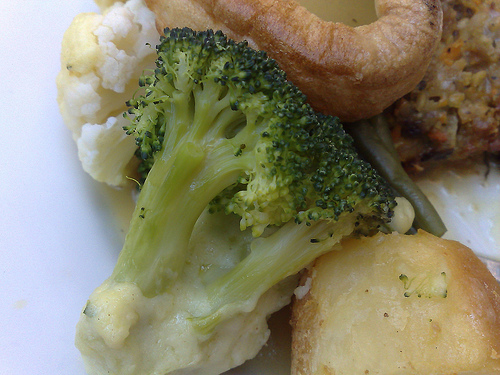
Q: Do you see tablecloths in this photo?
A: No, there are no tablecloths.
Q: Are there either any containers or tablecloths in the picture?
A: No, there are no tablecloths or containers.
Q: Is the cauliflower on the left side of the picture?
A: Yes, the cauliflower is on the left of the image.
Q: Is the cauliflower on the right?
A: No, the cauliflower is on the left of the image.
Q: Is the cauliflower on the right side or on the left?
A: The cauliflower is on the left of the image.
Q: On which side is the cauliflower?
A: The cauliflower is on the left of the image.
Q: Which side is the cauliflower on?
A: The cauliflower is on the left of the image.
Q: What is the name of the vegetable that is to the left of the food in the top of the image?
A: The vegetable is cauliflower.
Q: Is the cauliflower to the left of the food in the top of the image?
A: Yes, the cauliflower is to the left of the food.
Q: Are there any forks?
A: No, there are no forks.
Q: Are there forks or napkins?
A: No, there are no forks or napkins.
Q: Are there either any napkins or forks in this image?
A: No, there are no forks or napkins.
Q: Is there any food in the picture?
A: Yes, there is food.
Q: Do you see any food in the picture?
A: Yes, there is food.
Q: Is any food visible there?
A: Yes, there is food.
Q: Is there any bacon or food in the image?
A: Yes, there is food.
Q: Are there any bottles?
A: No, there are no bottles.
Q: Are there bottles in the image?
A: No, there are no bottles.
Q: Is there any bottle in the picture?
A: No, there are no bottles.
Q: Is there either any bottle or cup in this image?
A: No, there are no bottles or cups.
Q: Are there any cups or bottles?
A: No, there are no bottles or cups.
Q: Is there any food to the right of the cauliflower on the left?
A: Yes, there is food to the right of the cauliflower.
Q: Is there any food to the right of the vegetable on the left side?
A: Yes, there is food to the right of the cauliflower.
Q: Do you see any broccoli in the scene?
A: Yes, there is broccoli.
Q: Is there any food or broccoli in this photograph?
A: Yes, there is broccoli.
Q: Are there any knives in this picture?
A: No, there are no knives.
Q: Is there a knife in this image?
A: No, there are no knives.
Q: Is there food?
A: Yes, there is food.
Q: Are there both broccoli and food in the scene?
A: Yes, there are both food and broccoli.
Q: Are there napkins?
A: No, there are no napkins.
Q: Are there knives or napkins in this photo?
A: No, there are no napkins or knives.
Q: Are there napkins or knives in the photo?
A: No, there are no napkins or knives.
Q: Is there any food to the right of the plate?
A: Yes, there is food to the right of the plate.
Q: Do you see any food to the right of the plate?
A: Yes, there is food to the right of the plate.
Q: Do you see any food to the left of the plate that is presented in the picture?
A: No, the food is to the right of the plate.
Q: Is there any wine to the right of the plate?
A: No, there is food to the right of the plate.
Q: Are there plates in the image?
A: Yes, there is a plate.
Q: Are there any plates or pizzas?
A: Yes, there is a plate.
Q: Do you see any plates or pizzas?
A: Yes, there is a plate.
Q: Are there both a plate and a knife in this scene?
A: No, there is a plate but no knives.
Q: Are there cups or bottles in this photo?
A: No, there are no bottles or cups.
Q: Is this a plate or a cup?
A: This is a plate.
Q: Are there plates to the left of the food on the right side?
A: Yes, there is a plate to the left of the food.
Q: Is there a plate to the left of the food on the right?
A: Yes, there is a plate to the left of the food.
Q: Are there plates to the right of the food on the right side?
A: No, the plate is to the left of the food.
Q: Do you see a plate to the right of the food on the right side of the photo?
A: No, the plate is to the left of the food.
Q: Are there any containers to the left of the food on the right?
A: No, there is a plate to the left of the food.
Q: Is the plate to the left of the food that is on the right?
A: Yes, the plate is to the left of the food.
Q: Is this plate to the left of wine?
A: No, the plate is to the left of the food.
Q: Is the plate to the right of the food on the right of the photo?
A: No, the plate is to the left of the food.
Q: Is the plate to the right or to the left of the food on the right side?
A: The plate is to the left of the food.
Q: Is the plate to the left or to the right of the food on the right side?
A: The plate is to the left of the food.